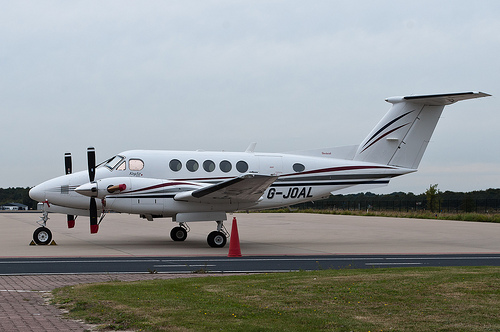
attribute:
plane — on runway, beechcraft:
[22, 84, 497, 253]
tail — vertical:
[317, 84, 494, 204]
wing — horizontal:
[173, 167, 281, 213]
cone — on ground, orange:
[223, 215, 247, 263]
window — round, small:
[165, 155, 186, 176]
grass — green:
[46, 262, 499, 332]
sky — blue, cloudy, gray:
[0, 1, 498, 192]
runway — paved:
[0, 204, 499, 280]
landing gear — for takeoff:
[26, 210, 235, 250]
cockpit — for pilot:
[80, 155, 165, 187]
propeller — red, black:
[86, 193, 108, 237]